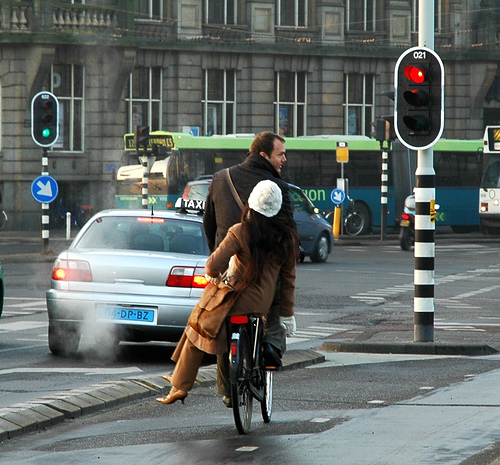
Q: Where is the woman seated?
A: Back of the bike.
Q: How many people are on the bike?
A: Two.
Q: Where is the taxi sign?
A: On top of the car.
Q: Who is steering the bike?
A: The man.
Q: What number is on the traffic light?
A: 021.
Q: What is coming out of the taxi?
A: Exhaust.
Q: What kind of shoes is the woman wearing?
A: High heels.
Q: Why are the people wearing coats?
A: It is cold.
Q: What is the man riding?
A: A bicycle.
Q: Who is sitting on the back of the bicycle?
A: A woman with a hat.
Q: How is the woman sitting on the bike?
A: Sideways.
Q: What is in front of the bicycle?
A: A gray car.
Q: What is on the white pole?
A: A traffic light.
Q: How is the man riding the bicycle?
A: He's standing.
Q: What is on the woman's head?
A: A white hat.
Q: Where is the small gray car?
A: Stopped at the light.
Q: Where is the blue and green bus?
A: Across the street.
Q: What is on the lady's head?
A: A hat.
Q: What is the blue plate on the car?
A: A license plate.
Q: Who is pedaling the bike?
A: The man.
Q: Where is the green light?
A: On the pole.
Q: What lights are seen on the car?
A: The brake lights.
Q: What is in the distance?
A: The building.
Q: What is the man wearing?
A: A coat.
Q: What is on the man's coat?
A: A strap.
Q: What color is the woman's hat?
A: White.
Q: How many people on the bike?
A: Two.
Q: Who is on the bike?
A: A man.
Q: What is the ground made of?
A: Cement.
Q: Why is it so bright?
A: Sunlight.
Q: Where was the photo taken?
A: Aside a city street.